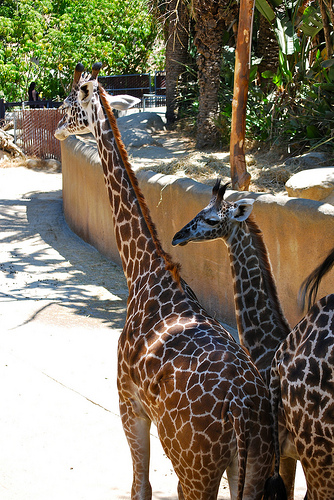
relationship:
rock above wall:
[285, 168, 334, 202] [62, 143, 95, 244]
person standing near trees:
[23, 77, 42, 109] [3, 1, 148, 99]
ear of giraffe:
[232, 198, 252, 221] [166, 175, 333, 498]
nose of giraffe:
[172, 228, 183, 239] [171, 177, 334, 500]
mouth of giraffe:
[175, 237, 189, 247] [171, 177, 334, 500]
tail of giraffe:
[270, 363, 293, 491] [53, 62, 273, 500]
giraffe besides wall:
[171, 177, 334, 500] [61, 147, 95, 230]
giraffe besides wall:
[53, 62, 273, 500] [61, 147, 95, 230]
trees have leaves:
[0, 0, 156, 119] [20, 13, 32, 30]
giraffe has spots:
[53, 62, 273, 500] [157, 335, 195, 375]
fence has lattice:
[17, 106, 60, 156] [32, 114, 47, 149]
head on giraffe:
[42, 60, 122, 144] [53, 62, 273, 500]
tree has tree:
[227, 0, 256, 191] [229, 0, 256, 191]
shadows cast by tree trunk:
[0, 193, 131, 330] [165, 0, 189, 131]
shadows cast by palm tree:
[0, 193, 131, 330] [192, 0, 239, 150]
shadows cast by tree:
[0, 193, 131, 330] [261, 0, 315, 157]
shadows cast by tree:
[0, 193, 131, 330] [227, 0, 256, 191]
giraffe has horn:
[53, 62, 273, 500] [90, 61, 102, 79]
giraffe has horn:
[53, 62, 273, 500] [71, 61, 83, 85]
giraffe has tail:
[53, 62, 273, 500] [229, 399, 250, 499]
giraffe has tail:
[171, 177, 334, 500] [262, 371, 286, 497]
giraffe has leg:
[53, 62, 273, 500] [118, 377, 151, 499]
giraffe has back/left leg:
[56, 80, 292, 497] [172, 462, 217, 498]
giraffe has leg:
[53, 62, 273, 500] [236, 442, 277, 498]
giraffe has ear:
[53, 62, 273, 500] [110, 92, 140, 116]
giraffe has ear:
[53, 62, 273, 500] [78, 77, 93, 106]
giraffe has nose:
[53, 62, 273, 500] [50, 125, 60, 135]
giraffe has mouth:
[53, 62, 273, 500] [53, 123, 59, 143]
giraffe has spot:
[53, 62, 273, 500] [143, 296, 161, 316]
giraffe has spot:
[53, 62, 273, 500] [147, 336, 164, 357]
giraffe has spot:
[53, 62, 273, 500] [184, 325, 200, 337]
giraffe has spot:
[53, 62, 273, 500] [172, 353, 192, 371]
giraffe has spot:
[53, 62, 273, 500] [161, 360, 174, 393]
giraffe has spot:
[166, 175, 333, 498] [256, 290, 269, 311]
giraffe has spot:
[166, 175, 333, 498] [239, 287, 259, 309]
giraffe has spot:
[166, 175, 333, 498] [260, 333, 281, 351]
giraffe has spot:
[166, 175, 333, 498] [255, 348, 276, 374]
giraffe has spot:
[166, 175, 333, 498] [259, 318, 277, 334]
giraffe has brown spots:
[171, 177, 334, 500] [282, 327, 332, 373]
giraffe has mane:
[171, 177, 334, 500] [245, 213, 294, 337]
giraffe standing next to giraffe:
[53, 62, 273, 500] [171, 177, 334, 500]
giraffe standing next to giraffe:
[171, 177, 334, 500] [171, 177, 334, 500]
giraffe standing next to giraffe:
[171, 177, 334, 500] [53, 62, 273, 500]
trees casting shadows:
[2, 2, 151, 91] [0, 193, 131, 330]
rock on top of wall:
[287, 164, 333, 210] [57, 129, 333, 343]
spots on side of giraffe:
[131, 316, 211, 378] [53, 62, 273, 500]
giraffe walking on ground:
[53, 62, 273, 500] [1, 162, 308, 498]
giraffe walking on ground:
[171, 177, 334, 500] [1, 162, 308, 498]